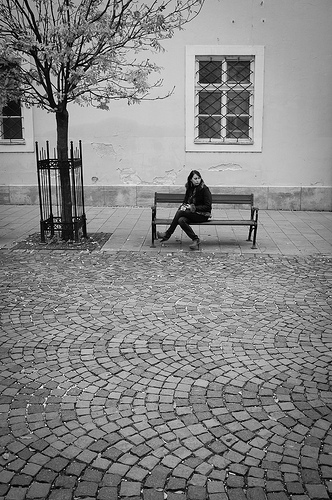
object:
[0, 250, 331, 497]
street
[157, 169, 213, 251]
lady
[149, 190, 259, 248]
bench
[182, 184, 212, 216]
jacket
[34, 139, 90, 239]
gate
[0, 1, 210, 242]
tree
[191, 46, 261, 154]
window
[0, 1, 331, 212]
wall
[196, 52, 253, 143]
wire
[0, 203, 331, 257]
sidewalk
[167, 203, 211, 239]
jeans